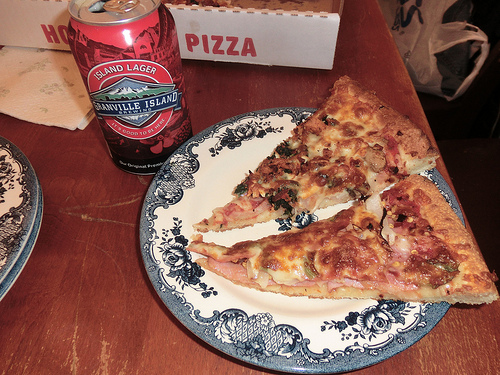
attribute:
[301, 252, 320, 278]
pepper — green 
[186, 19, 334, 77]
red lettering — red 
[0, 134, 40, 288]
plate — TWO STACKED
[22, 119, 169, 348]
wooden table — scrtached wooden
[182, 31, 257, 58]
word — PIZZA 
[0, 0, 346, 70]
box — SIDE 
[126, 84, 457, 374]
plate — white 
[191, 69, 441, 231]
pizza slice — TWO SLICES 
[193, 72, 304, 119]
table — wood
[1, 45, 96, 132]
napkin — white 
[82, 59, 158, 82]
lettering — white  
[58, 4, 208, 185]
can — red beer 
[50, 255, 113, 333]
table — BROWN WOODEN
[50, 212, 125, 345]
table — wood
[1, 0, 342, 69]
cardboard — box 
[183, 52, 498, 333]
pizza — slice 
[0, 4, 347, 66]
pizza box — WHITE , side, pizza 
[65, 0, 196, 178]
lager — can 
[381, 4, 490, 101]
plastic bag — WHITE PLASTIC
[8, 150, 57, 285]
dishes — stack 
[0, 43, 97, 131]
white napkin — WHITE 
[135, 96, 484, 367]
edges — blue design 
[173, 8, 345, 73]
box — pizza  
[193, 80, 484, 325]
pizza — two slices 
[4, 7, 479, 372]
table — wood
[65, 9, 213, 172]
beer — CAN 